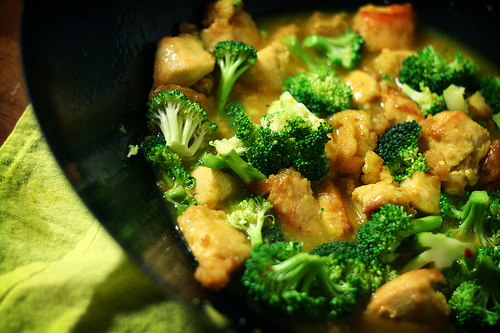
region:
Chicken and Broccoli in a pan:
[170, 43, 462, 321]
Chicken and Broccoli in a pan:
[144, 96, 264, 238]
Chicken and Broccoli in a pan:
[173, 146, 326, 296]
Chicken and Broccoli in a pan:
[282, 200, 410, 309]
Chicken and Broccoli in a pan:
[402, 230, 494, 265]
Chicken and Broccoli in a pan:
[365, 137, 485, 262]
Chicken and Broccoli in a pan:
[395, 66, 495, 259]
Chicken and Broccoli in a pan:
[260, 60, 370, 175]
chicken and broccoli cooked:
[142, 0, 496, 327]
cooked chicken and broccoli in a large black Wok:
[12, 0, 498, 331]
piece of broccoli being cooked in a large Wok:
[144, 87, 219, 157]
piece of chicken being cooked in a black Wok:
[148, 30, 220, 90]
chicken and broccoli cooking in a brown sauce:
[144, 0, 498, 331]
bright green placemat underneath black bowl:
[2, 99, 227, 330]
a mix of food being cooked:
[138, 0, 496, 330]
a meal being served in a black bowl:
[10, 0, 497, 332]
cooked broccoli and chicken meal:
[144, 0, 499, 332]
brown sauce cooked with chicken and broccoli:
[156, 8, 494, 320]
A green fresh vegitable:
[144, 91, 205, 151]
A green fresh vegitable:
[212, 37, 253, 119]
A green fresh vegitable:
[247, 105, 321, 159]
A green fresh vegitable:
[295, 24, 365, 66]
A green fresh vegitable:
[261, 83, 325, 191]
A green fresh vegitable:
[242, 243, 356, 313]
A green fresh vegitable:
[352, 200, 439, 258]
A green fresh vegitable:
[397, 45, 459, 105]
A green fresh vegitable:
[434, 187, 498, 241]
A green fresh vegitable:
[435, 268, 497, 316]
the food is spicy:
[202, 52, 432, 311]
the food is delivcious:
[236, 83, 413, 296]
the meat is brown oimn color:
[377, 279, 431, 319]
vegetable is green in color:
[284, 249, 321, 305]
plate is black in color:
[20, 52, 142, 203]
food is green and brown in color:
[257, 83, 404, 297]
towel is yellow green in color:
[12, 193, 104, 330]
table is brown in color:
[1, 55, 25, 105]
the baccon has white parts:
[169, 110, 195, 142]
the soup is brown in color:
[276, 222, 361, 242]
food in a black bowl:
[0, 6, 486, 321]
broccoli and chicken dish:
[135, 11, 486, 324]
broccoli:
[243, 225, 369, 312]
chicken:
[167, 200, 243, 290]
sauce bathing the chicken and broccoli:
[413, 27, 483, 58]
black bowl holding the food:
[21, 0, 252, 321]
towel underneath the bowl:
[1, 101, 227, 329]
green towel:
[0, 85, 225, 327]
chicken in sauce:
[255, 165, 360, 241]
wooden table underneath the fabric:
[2, 1, 24, 172]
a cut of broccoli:
[148, 79, 233, 160]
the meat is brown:
[410, 98, 488, 186]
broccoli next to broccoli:
[143, 79, 215, 156]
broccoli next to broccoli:
[209, 38, 255, 112]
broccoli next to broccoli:
[253, 86, 333, 185]